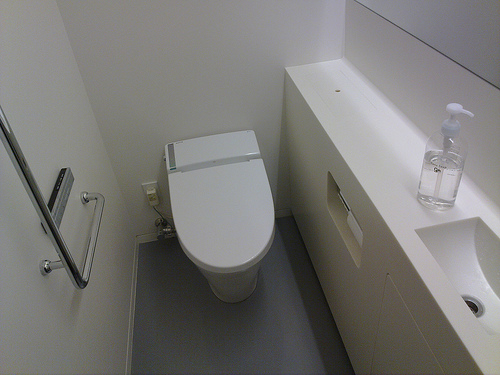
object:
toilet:
[162, 129, 277, 304]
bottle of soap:
[415, 102, 476, 212]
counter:
[282, 58, 499, 374]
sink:
[414, 216, 500, 353]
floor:
[125, 215, 358, 375]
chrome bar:
[0, 106, 107, 290]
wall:
[0, 1, 133, 374]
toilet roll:
[346, 211, 364, 249]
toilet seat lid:
[166, 157, 276, 273]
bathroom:
[2, 3, 500, 374]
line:
[349, 0, 500, 93]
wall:
[345, 4, 497, 198]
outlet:
[141, 181, 173, 230]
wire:
[152, 203, 173, 229]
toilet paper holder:
[335, 187, 366, 249]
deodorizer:
[41, 166, 76, 234]